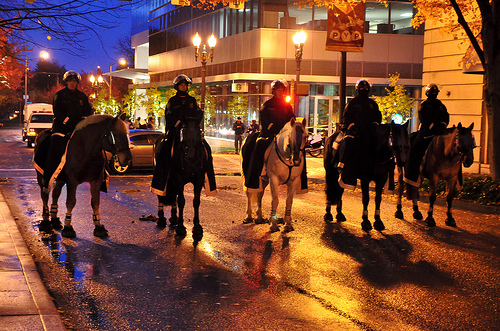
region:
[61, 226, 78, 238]
black color horse hoof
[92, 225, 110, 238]
black color horse hoof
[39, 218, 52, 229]
black color horse hoof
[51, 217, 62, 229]
black color horse hoof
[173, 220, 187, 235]
black color horse hoof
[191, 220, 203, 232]
black color horse hoof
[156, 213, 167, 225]
black color horse hoof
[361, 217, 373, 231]
black color horse hoof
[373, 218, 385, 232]
black color horse hoof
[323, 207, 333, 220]
black color horse hoof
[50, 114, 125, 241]
horse on the street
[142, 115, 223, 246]
horse on the street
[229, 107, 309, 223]
horse on the street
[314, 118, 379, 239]
horse on the street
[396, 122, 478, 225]
horse on the street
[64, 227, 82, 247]
hoof of the horse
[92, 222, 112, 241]
hoof of the horse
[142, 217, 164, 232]
hoof of the horse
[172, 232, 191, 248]
hoof of the horse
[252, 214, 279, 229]
hoof of the horse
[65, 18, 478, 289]
horse on the road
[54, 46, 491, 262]
horse wakling on the street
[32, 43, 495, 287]
horses walking in a fow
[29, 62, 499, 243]
horses walking in line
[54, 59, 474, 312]
horses carrying police officers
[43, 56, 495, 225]
horses carrying in officers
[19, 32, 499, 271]
officers riding the horses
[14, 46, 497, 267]
police officers riding horses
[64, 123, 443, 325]
a road that is wet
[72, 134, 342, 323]
a street that is wet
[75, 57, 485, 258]
horses walking on the raod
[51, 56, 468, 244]
horses walking on the street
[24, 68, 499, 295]
horses walking at night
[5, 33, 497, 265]
horses walkin goutside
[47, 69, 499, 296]
horses walking in a line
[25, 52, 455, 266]
officers riding the horses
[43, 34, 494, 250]
officers sitting on horses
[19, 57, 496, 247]
police officers on the horses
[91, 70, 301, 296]
vehicle on the road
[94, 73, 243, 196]
vehicle ont he street